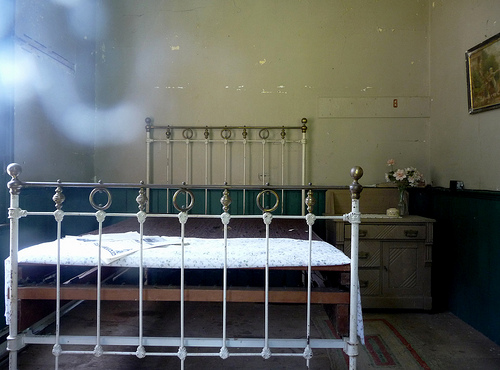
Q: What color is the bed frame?
A: White.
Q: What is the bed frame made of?
A: Metal.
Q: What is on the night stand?
A: A vase.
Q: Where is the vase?
A: On the nightstand.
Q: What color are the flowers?
A: White and yellow.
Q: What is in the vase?
A: Flowers.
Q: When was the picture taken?
A: Daytime.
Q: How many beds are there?
A: One.